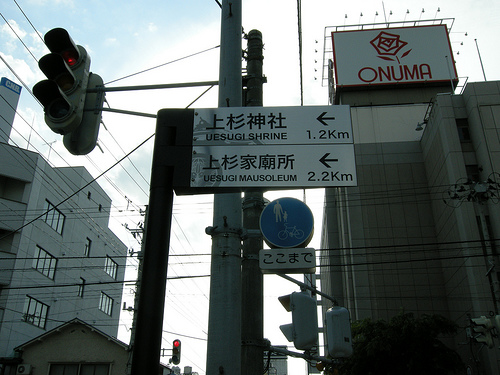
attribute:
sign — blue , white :
[256, 196, 313, 246]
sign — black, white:
[190, 102, 360, 194]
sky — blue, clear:
[81, 20, 208, 75]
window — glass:
[41, 200, 66, 232]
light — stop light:
[170, 337, 180, 364]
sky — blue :
[0, 9, 495, 358]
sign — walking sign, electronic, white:
[278, 291, 318, 348]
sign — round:
[255, 194, 313, 251]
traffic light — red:
[37, 28, 88, 127]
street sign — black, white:
[183, 102, 358, 191]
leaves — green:
[401, 314, 428, 341]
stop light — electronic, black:
[0, 31, 95, 126]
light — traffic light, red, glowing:
[170, 339, 182, 363]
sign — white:
[254, 240, 319, 276]